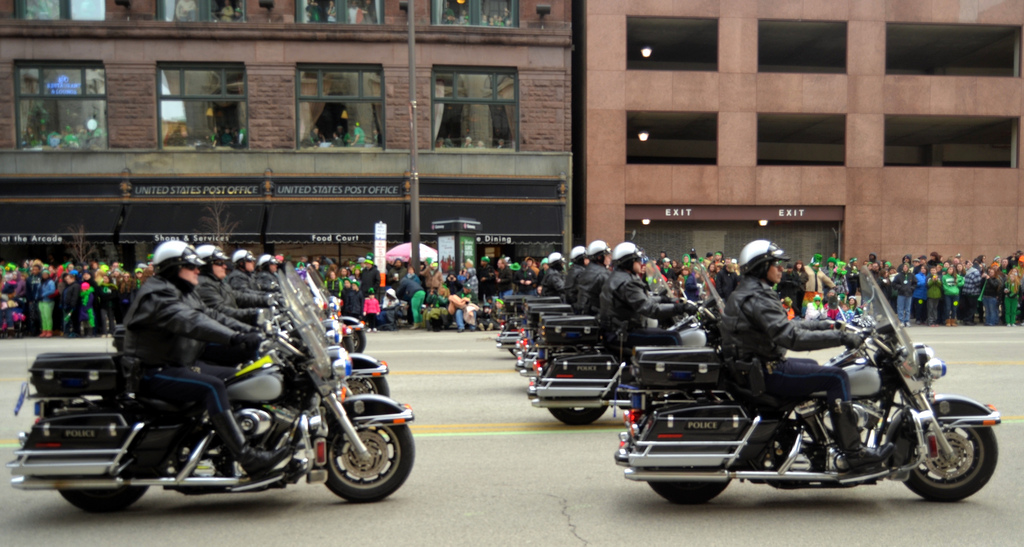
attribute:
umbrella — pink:
[373, 238, 463, 293]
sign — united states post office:
[134, 167, 569, 243]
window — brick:
[430, 64, 519, 148]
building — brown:
[13, 0, 573, 263]